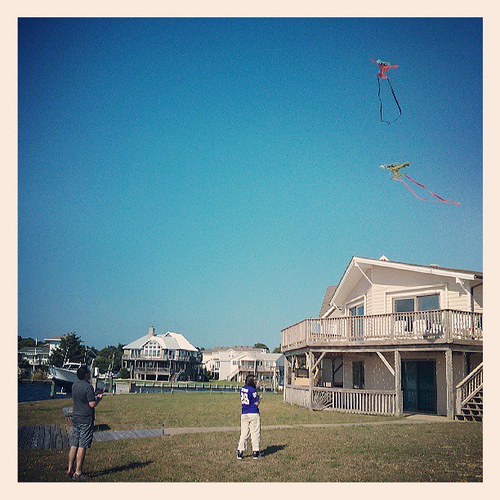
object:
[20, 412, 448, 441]
sidewalk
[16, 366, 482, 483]
yard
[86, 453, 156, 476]
shadow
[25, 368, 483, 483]
ground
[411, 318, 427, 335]
chair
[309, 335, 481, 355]
deck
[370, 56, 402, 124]
kite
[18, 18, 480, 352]
sky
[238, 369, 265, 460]
people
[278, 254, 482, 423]
house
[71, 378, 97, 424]
shirt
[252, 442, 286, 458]
shadow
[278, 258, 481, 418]
structure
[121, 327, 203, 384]
structure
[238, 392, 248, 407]
white numbers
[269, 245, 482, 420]
house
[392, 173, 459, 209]
string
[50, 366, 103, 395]
boat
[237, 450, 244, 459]
sneakers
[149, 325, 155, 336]
chimney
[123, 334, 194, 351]
roof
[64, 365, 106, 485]
guy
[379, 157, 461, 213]
kite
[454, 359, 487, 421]
stairs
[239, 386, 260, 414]
blue shirt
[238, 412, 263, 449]
gray pants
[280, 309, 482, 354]
fence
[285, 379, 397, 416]
fence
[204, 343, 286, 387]
house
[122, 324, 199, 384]
house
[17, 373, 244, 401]
body water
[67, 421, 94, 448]
shorts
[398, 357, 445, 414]
sliding door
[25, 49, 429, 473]
air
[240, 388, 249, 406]
numbers